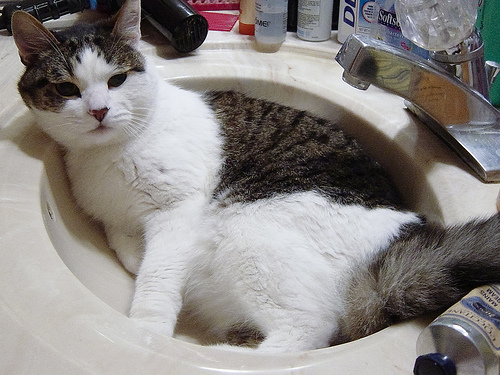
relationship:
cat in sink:
[8, 7, 388, 241] [37, 124, 416, 244]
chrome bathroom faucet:
[369, 58, 382, 69] [332, 12, 498, 172]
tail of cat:
[431, 211, 497, 283] [8, 7, 388, 241]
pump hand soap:
[373, 11, 396, 34] [371, 1, 440, 65]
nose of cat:
[90, 107, 109, 121] [8, 7, 388, 241]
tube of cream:
[254, 5, 282, 49] [235, 2, 266, 39]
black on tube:
[253, 19, 267, 27] [254, 5, 282, 49]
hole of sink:
[42, 204, 55, 222] [37, 124, 416, 244]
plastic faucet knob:
[424, 17, 438, 31] [393, 0, 489, 65]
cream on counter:
[235, 2, 266, 39] [213, 9, 317, 45]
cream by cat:
[235, 2, 266, 39] [8, 7, 388, 241]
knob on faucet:
[425, 28, 490, 64] [332, 12, 498, 172]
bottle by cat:
[253, 3, 285, 39] [8, 7, 388, 241]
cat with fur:
[8, 7, 388, 241] [78, 41, 98, 58]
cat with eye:
[8, 7, 388, 241] [106, 70, 127, 90]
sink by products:
[37, 124, 416, 244] [234, 3, 335, 50]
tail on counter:
[431, 211, 497, 283] [213, 9, 317, 45]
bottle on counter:
[253, 3, 285, 39] [213, 9, 317, 45]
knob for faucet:
[425, 28, 490, 64] [332, 12, 498, 172]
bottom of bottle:
[257, 27, 282, 55] [253, 3, 285, 39]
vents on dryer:
[190, 25, 204, 39] [141, 1, 220, 54]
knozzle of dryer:
[144, 6, 213, 53] [141, 1, 220, 54]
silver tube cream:
[268, 12, 276, 28] [235, 2, 266, 39]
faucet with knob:
[332, 12, 498, 172] [425, 28, 490, 64]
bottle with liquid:
[253, 3, 285, 39] [260, 12, 283, 35]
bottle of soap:
[253, 3, 285, 39] [371, 1, 440, 65]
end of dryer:
[170, 16, 209, 52] [141, 1, 220, 54]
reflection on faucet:
[356, 51, 373, 64] [332, 12, 498, 172]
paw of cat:
[130, 300, 176, 339] [8, 7, 388, 241]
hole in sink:
[42, 198, 59, 223] [37, 124, 416, 244]